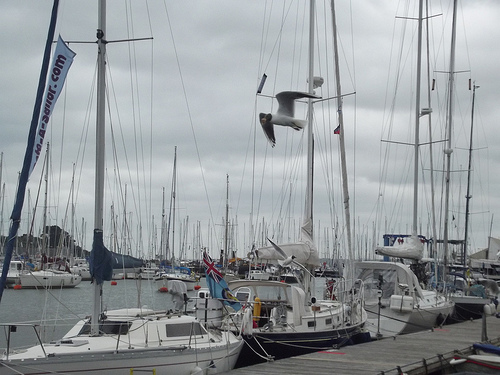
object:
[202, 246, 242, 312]
flag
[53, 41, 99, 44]
crosspiece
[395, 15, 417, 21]
crosspiece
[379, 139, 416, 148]
crosspiece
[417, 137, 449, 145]
crosspiece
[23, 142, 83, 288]
boat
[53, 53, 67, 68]
letters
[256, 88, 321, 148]
bird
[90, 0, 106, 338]
mast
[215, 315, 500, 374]
dock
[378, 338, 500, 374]
fence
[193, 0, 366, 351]
boat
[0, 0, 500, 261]
clouds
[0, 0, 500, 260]
gray sky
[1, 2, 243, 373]
boat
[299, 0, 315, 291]
mast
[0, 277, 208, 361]
water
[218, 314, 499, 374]
boardwalk